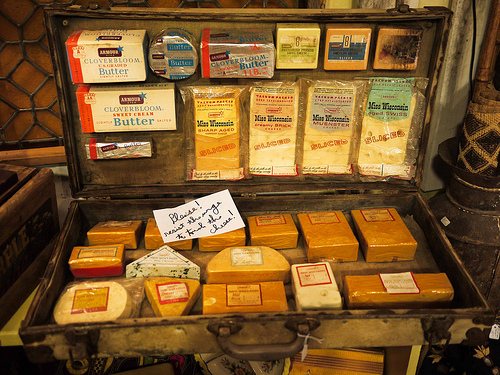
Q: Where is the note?
A: On top of the cheese.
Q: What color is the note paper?
A: White.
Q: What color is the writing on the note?
A: Black.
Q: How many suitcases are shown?
A: One.